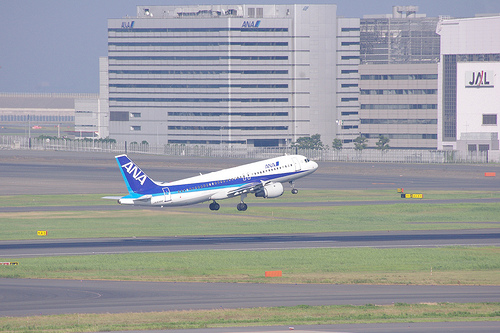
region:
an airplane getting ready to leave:
[101, 150, 319, 212]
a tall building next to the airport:
[101, 5, 352, 154]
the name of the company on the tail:
[123, 158, 148, 187]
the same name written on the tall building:
[235, 20, 262, 33]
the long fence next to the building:
[5, 128, 499, 173]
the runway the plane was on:
[3, 230, 490, 249]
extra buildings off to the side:
[343, 15, 499, 157]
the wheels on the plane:
[211, 198, 246, 217]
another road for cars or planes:
[16, 274, 492, 312]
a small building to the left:
[63, 97, 93, 138]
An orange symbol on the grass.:
[244, 245, 295, 283]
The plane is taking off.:
[68, 100, 355, 239]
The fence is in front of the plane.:
[250, 137, 430, 180]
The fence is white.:
[330, 137, 398, 178]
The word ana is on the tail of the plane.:
[97, 142, 159, 191]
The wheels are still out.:
[196, 167, 311, 213]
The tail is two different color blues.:
[92, 142, 167, 202]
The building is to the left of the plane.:
[89, 5, 351, 132]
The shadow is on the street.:
[107, 212, 424, 250]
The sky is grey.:
[16, 17, 86, 72]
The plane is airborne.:
[92, 126, 360, 229]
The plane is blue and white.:
[87, 130, 343, 219]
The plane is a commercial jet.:
[86, 127, 348, 223]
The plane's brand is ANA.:
[116, 152, 156, 191]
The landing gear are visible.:
[202, 190, 260, 218]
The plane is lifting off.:
[58, 124, 388, 256]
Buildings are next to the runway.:
[2, 1, 496, 157]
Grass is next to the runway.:
[0, 241, 497, 290]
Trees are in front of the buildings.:
[260, 123, 403, 162]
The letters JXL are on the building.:
[456, 61, 498, 95]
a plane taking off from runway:
[93, 136, 343, 227]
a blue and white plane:
[74, 147, 339, 217]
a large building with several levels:
[36, 5, 353, 152]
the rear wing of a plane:
[89, 145, 199, 229]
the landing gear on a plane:
[198, 170, 305, 230]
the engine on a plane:
[263, 172, 291, 201]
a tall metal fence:
[8, 127, 246, 155]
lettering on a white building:
[456, 68, 494, 105]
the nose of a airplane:
[288, 150, 323, 177]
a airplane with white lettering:
[93, 137, 329, 227]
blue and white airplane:
[100, 149, 321, 214]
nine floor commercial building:
[101, 13, 294, 155]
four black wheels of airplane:
[208, 201, 250, 213]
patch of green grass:
[343, 249, 388, 266]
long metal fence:
[3, 133, 498, 171]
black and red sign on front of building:
[459, 66, 499, 93]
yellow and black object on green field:
[392, 187, 432, 204]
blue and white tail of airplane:
[105, 151, 160, 191]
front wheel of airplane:
[286, 183, 305, 196]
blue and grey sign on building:
[235, 19, 268, 29]